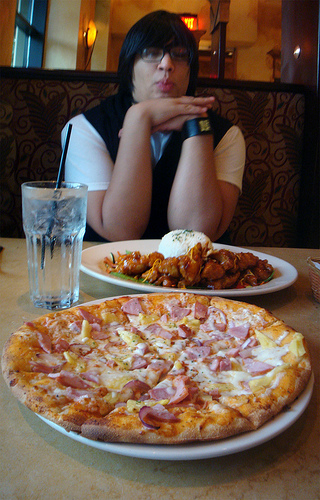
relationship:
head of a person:
[119, 9, 196, 96] [62, 9, 243, 241]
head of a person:
[119, 9, 195, 101] [62, 9, 243, 241]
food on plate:
[125, 244, 263, 281] [263, 280, 288, 291]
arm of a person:
[54, 93, 209, 233] [53, 7, 271, 234]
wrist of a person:
[114, 106, 154, 128] [105, 12, 235, 217]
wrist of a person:
[172, 117, 240, 141] [51, 25, 292, 230]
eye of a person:
[142, 48, 161, 60] [50, 4, 249, 246]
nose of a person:
[158, 52, 174, 72] [84, 8, 219, 155]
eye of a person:
[167, 52, 191, 65] [109, 13, 224, 196]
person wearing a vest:
[62, 9, 243, 241] [89, 106, 120, 135]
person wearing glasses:
[110, 13, 201, 140] [138, 42, 193, 68]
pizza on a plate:
[0, 291, 309, 445] [2, 292, 315, 461]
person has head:
[62, 9, 243, 241] [100, 21, 231, 133]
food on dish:
[125, 244, 151, 281] [88, 247, 205, 299]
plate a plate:
[65, 236, 299, 295] [75, 228, 300, 300]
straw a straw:
[50, 121, 73, 189] [50, 121, 73, 189]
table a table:
[18, 467, 307, 495] [18, 203, 307, 495]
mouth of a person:
[154, 78, 176, 92] [62, 9, 243, 241]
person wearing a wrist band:
[62, 9, 243, 241] [193, 120, 211, 152]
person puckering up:
[62, 9, 243, 241] [153, 77, 185, 120]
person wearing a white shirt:
[62, 9, 243, 241] [55, 101, 246, 195]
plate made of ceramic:
[65, 236, 299, 295] [67, 419, 111, 477]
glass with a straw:
[9, 160, 105, 283] [42, 92, 84, 169]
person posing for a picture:
[62, 9, 243, 241] [86, 122, 232, 226]